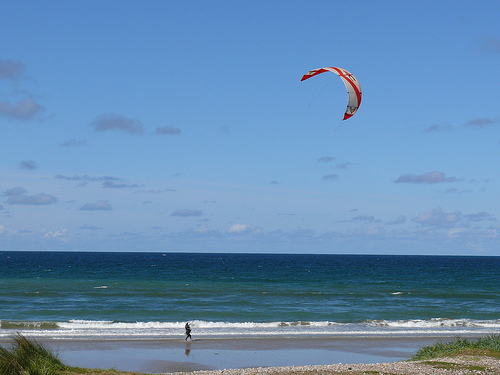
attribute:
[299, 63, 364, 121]
kite — in air, white, red, striped, existing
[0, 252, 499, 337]
water — wavy, blue, teal, existing, calm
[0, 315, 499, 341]
waves — white, existing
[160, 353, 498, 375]
gravel — grey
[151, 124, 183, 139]
cloud — grey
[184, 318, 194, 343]
person — existing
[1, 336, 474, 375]
sand — brown, grey, wet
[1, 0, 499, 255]
sky — blue, white, existing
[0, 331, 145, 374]
grass — green, patchy